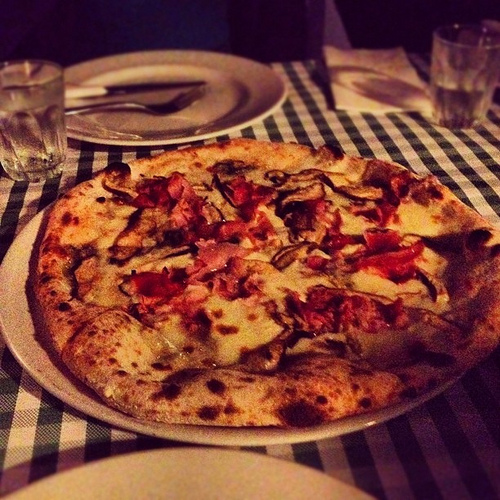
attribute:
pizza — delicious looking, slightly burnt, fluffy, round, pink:
[26, 136, 496, 429]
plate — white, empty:
[3, 195, 474, 446]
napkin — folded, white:
[319, 35, 438, 123]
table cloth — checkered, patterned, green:
[4, 46, 499, 322]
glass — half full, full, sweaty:
[426, 15, 497, 131]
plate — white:
[31, 46, 287, 148]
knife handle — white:
[50, 88, 108, 98]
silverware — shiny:
[52, 71, 215, 121]